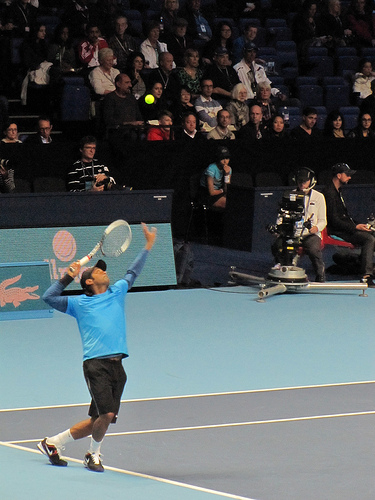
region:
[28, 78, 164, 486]
Tennis player hitting a tennis ball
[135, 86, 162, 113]
Tennis ball in the air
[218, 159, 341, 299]
Person with a headset and camera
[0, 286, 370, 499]
Tennis court is grey and blue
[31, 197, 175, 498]
Tennis player has a blue shirt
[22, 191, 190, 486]
Tennis player wears black short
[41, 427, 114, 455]
White socks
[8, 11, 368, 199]
Viewers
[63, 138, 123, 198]
Viewer wears a white and back sweter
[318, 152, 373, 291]
Man sits in a red chair wearing a cap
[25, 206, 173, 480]
Person with blue shirt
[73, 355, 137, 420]
Short is black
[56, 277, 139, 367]
T-shirt is blue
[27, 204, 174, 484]
Tennis player is position to hit a ball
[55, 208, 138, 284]
Tennis player has a racket in his right arm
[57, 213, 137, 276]
Racket has a white handle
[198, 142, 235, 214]
Viewer wears a blue shirt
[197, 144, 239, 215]
Person wears a cap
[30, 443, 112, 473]
Black shoes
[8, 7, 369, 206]
crowd watching tennis match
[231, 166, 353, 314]
cameraman filming tennis player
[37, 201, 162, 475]
tennis player serving ball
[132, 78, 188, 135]
yellow tennis ball in air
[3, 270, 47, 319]
alligator logo on wall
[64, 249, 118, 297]
tennis player wearing cap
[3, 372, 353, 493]
white lines on floor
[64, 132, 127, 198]
person wearing white striped shirt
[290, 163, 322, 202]
man wearing headset and cap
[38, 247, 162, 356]
tennis player wearing blue shirt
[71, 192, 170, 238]
White tennis racquet in man's hand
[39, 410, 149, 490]
Man wearing black Nikes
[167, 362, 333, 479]
Tennis court is gray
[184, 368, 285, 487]
White lines on court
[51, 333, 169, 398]
Man wearing black shorts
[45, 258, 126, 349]
Man wearing blue shirt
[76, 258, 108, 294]
Man wearing dark hat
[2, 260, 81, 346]
Alligator on back wall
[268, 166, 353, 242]
Cameraman wearing white shirt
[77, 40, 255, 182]
Many people watching tennis match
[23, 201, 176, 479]
Tennis player wears blue shirt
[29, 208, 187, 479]
Tennis player holds hands up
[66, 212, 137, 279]
Tennis racket is tan and white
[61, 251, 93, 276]
Handle of tennis racket is white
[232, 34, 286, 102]
Man wears a white jacket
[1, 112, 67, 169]
Couple wears glasses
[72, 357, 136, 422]
Black short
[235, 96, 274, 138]
Person wears a black jacket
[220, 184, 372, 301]
Professional camera is on a mobile support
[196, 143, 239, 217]
Girl wears a blue t-shirt